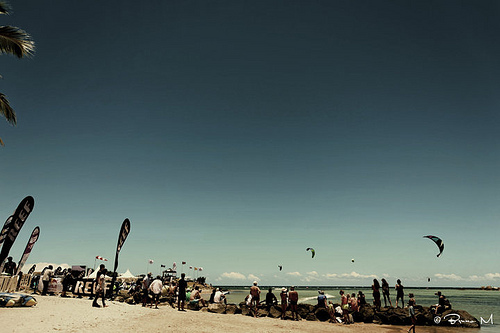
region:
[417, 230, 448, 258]
black and white kite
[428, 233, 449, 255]
kite flying in the air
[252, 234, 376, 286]
kites flying in the air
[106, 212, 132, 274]
white and black flags on ground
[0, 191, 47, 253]
white and black markers on ground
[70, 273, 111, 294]
black and white sign on ground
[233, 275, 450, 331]
group of people on the beach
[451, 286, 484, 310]
ocean water in background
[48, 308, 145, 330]
white sand on the beach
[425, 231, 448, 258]
black and white kite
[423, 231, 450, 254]
black kite in the air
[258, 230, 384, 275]
kites flying in the air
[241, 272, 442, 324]
people standing on the beach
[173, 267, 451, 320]
people spectating the event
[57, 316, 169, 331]
white sand on the beach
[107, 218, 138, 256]
black and white flag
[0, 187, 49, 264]
black and white flags on beach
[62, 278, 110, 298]
black sign on wall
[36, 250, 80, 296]
people leaning on fence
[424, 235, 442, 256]
kite in the air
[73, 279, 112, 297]
an advertisement poster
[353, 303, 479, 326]
large rock by the water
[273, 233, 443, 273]
kites in the air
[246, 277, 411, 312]
people watching the kites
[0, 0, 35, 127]
palm tree branches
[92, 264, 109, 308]
people walking on the beach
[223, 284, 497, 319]
ocean water is calm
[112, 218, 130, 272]
brand flag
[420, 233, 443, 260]
a parasail flying in the air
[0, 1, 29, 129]
the right edge of a palm tree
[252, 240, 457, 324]
a crowd of people on the beach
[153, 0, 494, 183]
a dark blue sky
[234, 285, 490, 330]
a sandy beach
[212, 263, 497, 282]
a strip of low flying clouds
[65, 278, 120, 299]
a large sign with white text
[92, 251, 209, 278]
a group of distant flags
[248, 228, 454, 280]
a sky full of sails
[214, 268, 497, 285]
Clouds on the horizon.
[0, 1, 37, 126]
The tips of palm tree fronds.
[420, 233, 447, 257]
A kite above a body of water.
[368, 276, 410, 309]
People standing on large rocks.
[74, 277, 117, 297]
An advertising sign.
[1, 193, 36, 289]
A wind resistant sign that says "REEF".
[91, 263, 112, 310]
Two people walking on the beach.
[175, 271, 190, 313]
A man standing on the beach watching kites fly.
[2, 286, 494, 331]
A sandy beach.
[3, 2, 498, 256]
A cloudless blue sky.